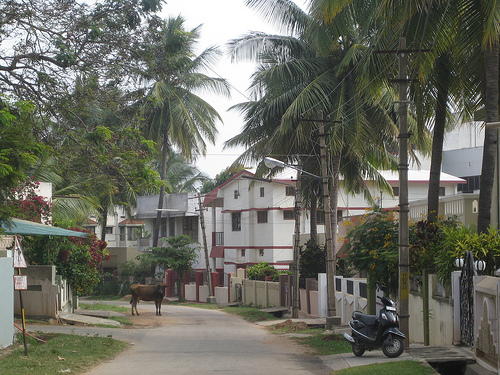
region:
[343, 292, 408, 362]
scooter parked in front of gate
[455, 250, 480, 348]
the gate is black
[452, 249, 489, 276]
lights on either side of gate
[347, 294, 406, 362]
the scooter is black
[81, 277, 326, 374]
cow standing in road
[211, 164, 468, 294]
the house is white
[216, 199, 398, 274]
house has red frames on it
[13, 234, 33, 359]
white sign in grass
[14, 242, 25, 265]
person standing on sign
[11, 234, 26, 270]
sign is triangular shaped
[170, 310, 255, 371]
road vehicles travel on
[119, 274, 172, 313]
cow on side of road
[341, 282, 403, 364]
motorized bike in drive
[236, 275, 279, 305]
fence around the yard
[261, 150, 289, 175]
light on the pole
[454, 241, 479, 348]
gate to the home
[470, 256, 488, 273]
light near the gate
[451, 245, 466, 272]
light near the gate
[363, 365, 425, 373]
grass near the drive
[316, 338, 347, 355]
grass near the drive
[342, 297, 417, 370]
motor scooter in driveway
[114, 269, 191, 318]
brown cow standing next to road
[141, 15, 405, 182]
palm trees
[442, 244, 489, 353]
black metal gate in stone wall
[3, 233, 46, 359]
street signs on yellow and black pole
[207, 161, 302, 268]
white house with red trim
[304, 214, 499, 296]
plants next to wall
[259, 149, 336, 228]
street light extending from pole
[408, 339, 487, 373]
ramp over a road side ditch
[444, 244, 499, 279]
lamps at edge of gate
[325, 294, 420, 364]
this is a bike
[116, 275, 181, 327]
this is a cow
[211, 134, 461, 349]
this is a house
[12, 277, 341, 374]
this is a street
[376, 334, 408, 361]
this is a wheel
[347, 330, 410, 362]
these are the wheels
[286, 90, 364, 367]
this is a pole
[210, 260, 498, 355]
this is a wall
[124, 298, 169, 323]
these are the legs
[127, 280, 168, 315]
Brown cow standing beside a street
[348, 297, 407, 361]
Black motorcyle parked on a concrete pad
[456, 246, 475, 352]
Decorative black metal fence door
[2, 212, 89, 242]
Part of a green awning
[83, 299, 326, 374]
Narrow curved street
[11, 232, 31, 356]
Pole with a triangular sign on top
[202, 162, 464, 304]
White building with red accents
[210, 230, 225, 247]
Black balcony railing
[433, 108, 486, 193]
Tall building on a different street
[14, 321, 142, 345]
Side street on the left